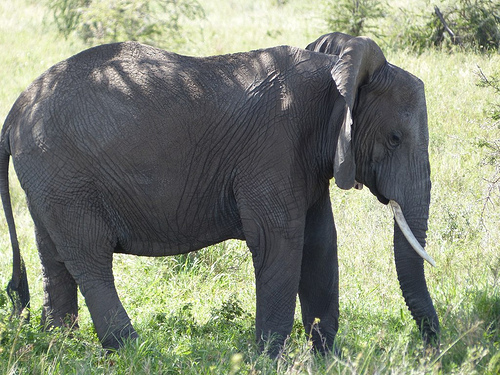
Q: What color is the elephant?
A: Grey.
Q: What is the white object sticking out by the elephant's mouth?
A: Tusk.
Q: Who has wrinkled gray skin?
A: The elephant.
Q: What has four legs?
A: The elephant.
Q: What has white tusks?
A: The elephant.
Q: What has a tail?
A: The elephant.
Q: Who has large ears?
A: The elephant.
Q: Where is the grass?
A: Under the elephant.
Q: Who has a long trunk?
A: The elephant.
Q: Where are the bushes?
A: Behind the elephant.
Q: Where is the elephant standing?
A: In the grass.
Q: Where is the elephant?
A: On the grass.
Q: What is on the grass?
A: The elephant.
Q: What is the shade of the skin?
A: Gray.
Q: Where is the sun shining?
A: On the back of the animal.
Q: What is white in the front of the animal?
A: The tusks.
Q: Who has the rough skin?
A: The elephant.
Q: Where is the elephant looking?
A: Down towards the grass.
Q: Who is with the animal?
A: Nobody is with the elephant.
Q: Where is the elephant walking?
A: To the right.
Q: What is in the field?
A: An elephant.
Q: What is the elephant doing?
A: Walking.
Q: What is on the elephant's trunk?
A: A tusk.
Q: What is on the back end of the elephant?
A: A tail.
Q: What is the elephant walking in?
A: Grass.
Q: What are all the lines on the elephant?
A: Wrinkles.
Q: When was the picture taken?
A: In the daytime.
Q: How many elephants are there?
A: One.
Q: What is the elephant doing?
A: Walking.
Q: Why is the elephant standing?
A: To walk.